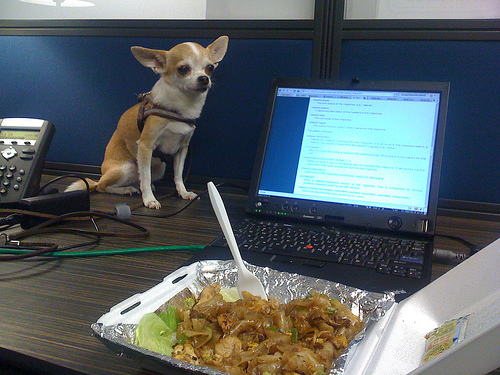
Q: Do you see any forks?
A: Yes, there is a fork.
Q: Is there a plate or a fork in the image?
A: Yes, there is a fork.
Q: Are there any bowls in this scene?
A: No, there are no bowls.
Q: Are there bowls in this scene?
A: No, there are no bowls.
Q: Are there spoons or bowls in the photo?
A: No, there are no bowls or spoons.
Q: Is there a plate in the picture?
A: No, there are no plates.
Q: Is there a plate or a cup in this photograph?
A: No, there are no plates or cups.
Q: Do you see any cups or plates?
A: No, there are no plates or cups.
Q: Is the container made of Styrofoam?
A: Yes, the container is made of styrofoam.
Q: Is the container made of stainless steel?
A: No, the container is made of styrofoam.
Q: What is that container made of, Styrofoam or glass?
A: The container is made of styrofoam.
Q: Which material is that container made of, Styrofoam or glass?
A: The container is made of styrofoam.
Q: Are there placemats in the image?
A: No, there are no placemats.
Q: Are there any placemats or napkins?
A: No, there are no placemats or napkins.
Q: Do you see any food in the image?
A: Yes, there is food.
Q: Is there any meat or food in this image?
A: Yes, there is food.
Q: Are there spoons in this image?
A: No, there are no spoons.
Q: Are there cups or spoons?
A: No, there are no spoons or cups.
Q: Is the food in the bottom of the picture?
A: Yes, the food is in the bottom of the image.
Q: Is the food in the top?
A: No, the food is in the bottom of the image.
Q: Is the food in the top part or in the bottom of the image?
A: The food is in the bottom of the image.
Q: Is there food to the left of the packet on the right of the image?
A: Yes, there is food to the left of the packet.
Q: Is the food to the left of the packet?
A: Yes, the food is to the left of the packet.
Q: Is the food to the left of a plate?
A: No, the food is to the left of the packet.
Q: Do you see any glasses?
A: No, there are no glasses.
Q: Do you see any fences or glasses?
A: No, there are no glasses or fences.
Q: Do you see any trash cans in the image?
A: No, there are no trash cans.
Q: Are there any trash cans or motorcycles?
A: No, there are no trash cans or motorcycles.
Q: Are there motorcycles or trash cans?
A: No, there are no trash cans or motorcycles.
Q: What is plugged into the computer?
A: The cable is plugged into the computer.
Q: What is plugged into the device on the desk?
A: The cable is plugged into the computer.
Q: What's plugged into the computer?
A: The cable is plugged into the computer.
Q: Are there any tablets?
A: No, there are no tablets.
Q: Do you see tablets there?
A: No, there are no tablets.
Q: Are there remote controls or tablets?
A: No, there are no tablets or remote controls.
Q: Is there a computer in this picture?
A: Yes, there is a computer.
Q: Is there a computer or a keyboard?
A: Yes, there is a computer.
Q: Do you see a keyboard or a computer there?
A: Yes, there is a computer.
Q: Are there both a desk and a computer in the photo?
A: Yes, there are both a computer and a desk.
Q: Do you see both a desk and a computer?
A: Yes, there are both a computer and a desk.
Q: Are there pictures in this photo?
A: No, there are no pictures.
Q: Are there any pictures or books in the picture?
A: No, there are no pictures or books.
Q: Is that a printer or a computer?
A: That is a computer.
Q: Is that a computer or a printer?
A: That is a computer.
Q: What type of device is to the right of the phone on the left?
A: The device is a computer.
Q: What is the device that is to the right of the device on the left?
A: The device is a computer.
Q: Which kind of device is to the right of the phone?
A: The device is a computer.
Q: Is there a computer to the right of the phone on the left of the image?
A: Yes, there is a computer to the right of the phone.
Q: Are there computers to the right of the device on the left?
A: Yes, there is a computer to the right of the phone.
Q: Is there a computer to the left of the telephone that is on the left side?
A: No, the computer is to the right of the phone.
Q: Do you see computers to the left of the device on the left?
A: No, the computer is to the right of the phone.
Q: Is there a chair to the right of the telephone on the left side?
A: No, there is a computer to the right of the telephone.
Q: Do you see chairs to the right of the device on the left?
A: No, there is a computer to the right of the telephone.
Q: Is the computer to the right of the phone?
A: Yes, the computer is to the right of the phone.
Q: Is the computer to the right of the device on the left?
A: Yes, the computer is to the right of the phone.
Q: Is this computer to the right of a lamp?
A: No, the computer is to the right of the phone.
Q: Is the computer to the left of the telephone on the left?
A: No, the computer is to the right of the telephone.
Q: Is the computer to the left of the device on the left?
A: No, the computer is to the right of the telephone.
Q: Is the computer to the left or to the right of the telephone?
A: The computer is to the right of the telephone.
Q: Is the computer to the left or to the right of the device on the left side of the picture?
A: The computer is to the right of the telephone.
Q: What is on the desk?
A: The computer is on the desk.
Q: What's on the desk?
A: The computer is on the desk.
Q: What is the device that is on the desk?
A: The device is a computer.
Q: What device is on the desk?
A: The device is a computer.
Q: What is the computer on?
A: The computer is on the desk.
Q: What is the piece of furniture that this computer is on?
A: The piece of furniture is a desk.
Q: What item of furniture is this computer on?
A: The computer is on the desk.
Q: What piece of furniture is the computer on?
A: The computer is on the desk.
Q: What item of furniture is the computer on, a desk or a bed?
A: The computer is on a desk.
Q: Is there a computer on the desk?
A: Yes, there is a computer on the desk.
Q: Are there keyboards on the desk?
A: No, there is a computer on the desk.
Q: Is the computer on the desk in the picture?
A: Yes, the computer is on the desk.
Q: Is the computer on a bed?
A: No, the computer is on the desk.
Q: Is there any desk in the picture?
A: Yes, there is a desk.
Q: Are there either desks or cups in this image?
A: Yes, there is a desk.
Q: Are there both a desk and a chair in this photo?
A: No, there is a desk but no chairs.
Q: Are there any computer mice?
A: No, there are no computer mice.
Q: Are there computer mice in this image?
A: No, there are no computer mice.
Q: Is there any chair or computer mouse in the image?
A: No, there are no computer mice or chairs.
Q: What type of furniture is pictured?
A: The furniture is a desk.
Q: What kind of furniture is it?
A: The piece of furniture is a desk.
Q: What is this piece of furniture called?
A: That is a desk.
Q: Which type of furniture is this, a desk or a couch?
A: That is a desk.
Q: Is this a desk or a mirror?
A: This is a desk.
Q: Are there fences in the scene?
A: No, there are no fences.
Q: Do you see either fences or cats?
A: No, there are no fences or cats.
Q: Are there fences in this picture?
A: No, there are no fences.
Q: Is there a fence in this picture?
A: No, there are no fences.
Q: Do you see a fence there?
A: No, there are no fences.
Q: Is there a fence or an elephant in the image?
A: No, there are no fences or elephants.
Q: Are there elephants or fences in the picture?
A: No, there are no fences or elephants.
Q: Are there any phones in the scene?
A: Yes, there is a phone.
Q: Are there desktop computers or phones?
A: Yes, there is a phone.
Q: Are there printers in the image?
A: No, there are no printers.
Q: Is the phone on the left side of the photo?
A: Yes, the phone is on the left of the image.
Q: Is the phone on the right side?
A: No, the phone is on the left of the image.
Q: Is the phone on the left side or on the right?
A: The phone is on the left of the image.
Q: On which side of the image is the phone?
A: The phone is on the left of the image.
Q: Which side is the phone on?
A: The phone is on the left of the image.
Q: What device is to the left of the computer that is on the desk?
A: The device is a phone.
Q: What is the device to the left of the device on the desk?
A: The device is a phone.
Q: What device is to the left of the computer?
A: The device is a phone.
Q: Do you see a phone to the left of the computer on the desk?
A: Yes, there is a phone to the left of the computer.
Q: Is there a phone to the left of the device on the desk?
A: Yes, there is a phone to the left of the computer.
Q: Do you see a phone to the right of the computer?
A: No, the phone is to the left of the computer.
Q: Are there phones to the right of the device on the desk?
A: No, the phone is to the left of the computer.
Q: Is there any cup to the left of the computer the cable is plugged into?
A: No, there is a phone to the left of the computer.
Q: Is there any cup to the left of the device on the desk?
A: No, there is a phone to the left of the computer.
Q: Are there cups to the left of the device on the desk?
A: No, there is a phone to the left of the computer.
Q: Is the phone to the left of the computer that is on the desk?
A: Yes, the phone is to the left of the computer.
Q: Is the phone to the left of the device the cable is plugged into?
A: Yes, the phone is to the left of the computer.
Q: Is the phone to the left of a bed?
A: No, the phone is to the left of the computer.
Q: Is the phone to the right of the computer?
A: No, the phone is to the left of the computer.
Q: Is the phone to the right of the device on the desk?
A: No, the phone is to the left of the computer.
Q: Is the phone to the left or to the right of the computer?
A: The phone is to the left of the computer.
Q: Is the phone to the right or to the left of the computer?
A: The phone is to the left of the computer.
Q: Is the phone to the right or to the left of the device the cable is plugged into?
A: The phone is to the left of the computer.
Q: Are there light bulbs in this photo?
A: No, there are no light bulbs.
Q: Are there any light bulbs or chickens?
A: No, there are no light bulbs or chickens.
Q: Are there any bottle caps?
A: No, there are no bottle caps.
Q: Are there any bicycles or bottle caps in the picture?
A: No, there are no bottle caps or bicycles.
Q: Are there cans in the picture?
A: No, there are no cans.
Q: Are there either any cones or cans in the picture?
A: No, there are no cans or cones.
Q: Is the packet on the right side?
A: Yes, the packet is on the right of the image.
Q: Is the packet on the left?
A: No, the packet is on the right of the image.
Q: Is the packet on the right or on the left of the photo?
A: The packet is on the right of the image.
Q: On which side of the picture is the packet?
A: The packet is on the right of the image.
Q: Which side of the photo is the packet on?
A: The packet is on the right of the image.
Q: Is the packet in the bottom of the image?
A: Yes, the packet is in the bottom of the image.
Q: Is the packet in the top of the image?
A: No, the packet is in the bottom of the image.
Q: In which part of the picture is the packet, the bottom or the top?
A: The packet is in the bottom of the image.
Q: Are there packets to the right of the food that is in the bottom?
A: Yes, there is a packet to the right of the food.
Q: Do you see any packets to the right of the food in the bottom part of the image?
A: Yes, there is a packet to the right of the food.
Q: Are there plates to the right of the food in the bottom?
A: No, there is a packet to the right of the food.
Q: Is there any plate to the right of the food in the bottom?
A: No, there is a packet to the right of the food.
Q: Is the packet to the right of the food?
A: Yes, the packet is to the right of the food.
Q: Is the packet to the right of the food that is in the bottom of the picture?
A: Yes, the packet is to the right of the food.